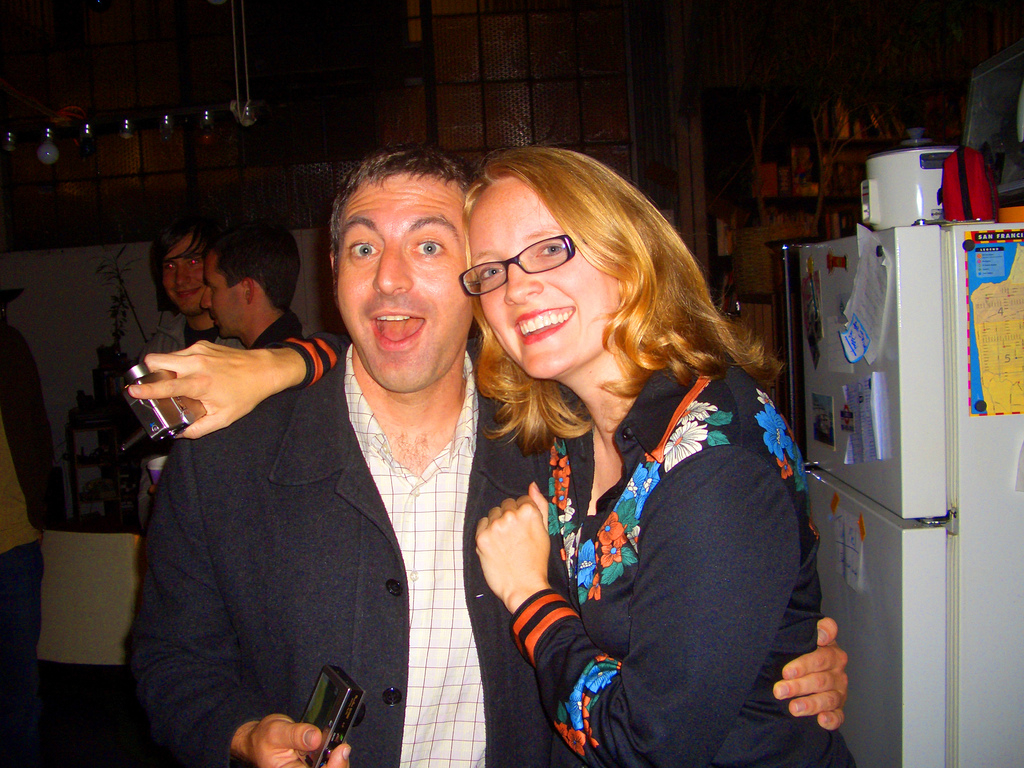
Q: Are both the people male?
A: No, they are both male and female.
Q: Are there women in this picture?
A: Yes, there is a woman.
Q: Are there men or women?
A: Yes, there is a woman.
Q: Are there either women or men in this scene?
A: Yes, there is a woman.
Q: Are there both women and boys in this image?
A: No, there is a woman but no boys.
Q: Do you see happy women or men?
A: Yes, there is a happy woman.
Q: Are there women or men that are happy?
A: Yes, the woman is happy.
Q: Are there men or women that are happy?
A: Yes, the woman is happy.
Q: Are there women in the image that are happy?
A: Yes, there is a happy woman.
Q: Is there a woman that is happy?
A: Yes, there is a woman that is happy.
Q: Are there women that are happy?
A: Yes, there is a woman that is happy.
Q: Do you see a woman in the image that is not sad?
A: Yes, there is a happy woman.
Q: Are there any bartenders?
A: No, there are no bartenders.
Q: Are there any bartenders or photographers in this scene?
A: No, there are no bartenders or photographers.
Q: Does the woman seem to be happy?
A: Yes, the woman is happy.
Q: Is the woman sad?
A: No, the woman is happy.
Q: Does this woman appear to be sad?
A: No, the woman is happy.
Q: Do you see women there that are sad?
A: No, there is a woman but she is happy.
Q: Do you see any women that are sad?
A: No, there is a woman but she is happy.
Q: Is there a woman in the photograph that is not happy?
A: No, there is a woman but she is happy.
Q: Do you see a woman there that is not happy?
A: No, there is a woman but she is happy.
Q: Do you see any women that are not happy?
A: No, there is a woman but she is happy.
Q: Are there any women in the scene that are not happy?
A: No, there is a woman but she is happy.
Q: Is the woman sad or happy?
A: The woman is happy.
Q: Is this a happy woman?
A: Yes, this is a happy woman.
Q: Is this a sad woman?
A: No, this is a happy woman.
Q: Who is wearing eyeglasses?
A: The woman is wearing eyeglasses.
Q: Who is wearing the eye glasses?
A: The woman is wearing eyeglasses.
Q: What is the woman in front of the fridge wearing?
A: The woman is wearing eyeglasses.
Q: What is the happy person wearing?
A: The woman is wearing eyeglasses.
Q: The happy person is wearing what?
A: The woman is wearing eyeglasses.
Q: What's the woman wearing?
A: The woman is wearing eyeglasses.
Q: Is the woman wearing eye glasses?
A: Yes, the woman is wearing eye glasses.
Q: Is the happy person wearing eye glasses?
A: Yes, the woman is wearing eye glasses.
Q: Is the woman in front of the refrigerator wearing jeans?
A: No, the woman is wearing eye glasses.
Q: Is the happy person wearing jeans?
A: No, the woman is wearing eye glasses.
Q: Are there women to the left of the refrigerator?
A: Yes, there is a woman to the left of the refrigerator.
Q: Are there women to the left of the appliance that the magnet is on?
A: Yes, there is a woman to the left of the refrigerator.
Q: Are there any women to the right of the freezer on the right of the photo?
A: No, the woman is to the left of the freezer.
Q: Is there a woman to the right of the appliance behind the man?
A: No, the woman is to the left of the freezer.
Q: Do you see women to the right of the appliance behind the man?
A: No, the woman is to the left of the freezer.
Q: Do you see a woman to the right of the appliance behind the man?
A: No, the woman is to the left of the freezer.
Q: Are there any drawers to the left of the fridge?
A: No, there is a woman to the left of the fridge.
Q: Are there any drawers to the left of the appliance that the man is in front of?
A: No, there is a woman to the left of the fridge.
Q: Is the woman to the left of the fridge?
A: Yes, the woman is to the left of the fridge.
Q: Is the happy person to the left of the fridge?
A: Yes, the woman is to the left of the fridge.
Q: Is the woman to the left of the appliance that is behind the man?
A: Yes, the woman is to the left of the fridge.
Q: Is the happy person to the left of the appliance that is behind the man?
A: Yes, the woman is to the left of the fridge.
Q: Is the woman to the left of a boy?
A: No, the woman is to the left of the fridge.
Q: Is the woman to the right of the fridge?
A: No, the woman is to the left of the fridge.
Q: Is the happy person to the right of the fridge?
A: No, the woman is to the left of the fridge.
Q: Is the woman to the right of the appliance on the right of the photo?
A: No, the woman is to the left of the fridge.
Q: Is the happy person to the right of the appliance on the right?
A: No, the woman is to the left of the fridge.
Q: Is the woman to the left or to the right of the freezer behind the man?
A: The woman is to the left of the refrigerator.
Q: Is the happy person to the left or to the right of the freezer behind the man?
A: The woman is to the left of the refrigerator.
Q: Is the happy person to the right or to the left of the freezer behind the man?
A: The woman is to the left of the refrigerator.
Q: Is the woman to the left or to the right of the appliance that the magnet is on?
A: The woman is to the left of the refrigerator.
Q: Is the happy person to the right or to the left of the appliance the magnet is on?
A: The woman is to the left of the refrigerator.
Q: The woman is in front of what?
A: The woman is in front of the fridge.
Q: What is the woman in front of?
A: The woman is in front of the fridge.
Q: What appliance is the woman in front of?
A: The woman is in front of the refrigerator.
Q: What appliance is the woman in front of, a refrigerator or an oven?
A: The woman is in front of a refrigerator.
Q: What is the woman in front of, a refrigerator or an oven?
A: The woman is in front of a refrigerator.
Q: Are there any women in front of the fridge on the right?
A: Yes, there is a woman in front of the refrigerator.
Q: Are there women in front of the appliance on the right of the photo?
A: Yes, there is a woman in front of the refrigerator.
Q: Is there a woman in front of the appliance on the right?
A: Yes, there is a woman in front of the refrigerator.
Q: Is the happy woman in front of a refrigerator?
A: Yes, the woman is in front of a refrigerator.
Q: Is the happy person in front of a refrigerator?
A: Yes, the woman is in front of a refrigerator.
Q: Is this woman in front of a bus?
A: No, the woman is in front of a refrigerator.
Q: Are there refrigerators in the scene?
A: Yes, there is a refrigerator.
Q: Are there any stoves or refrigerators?
A: Yes, there is a refrigerator.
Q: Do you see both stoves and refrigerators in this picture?
A: No, there is a refrigerator but no stoves.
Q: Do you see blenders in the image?
A: No, there are no blenders.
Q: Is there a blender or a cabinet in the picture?
A: No, there are no blenders or cabinets.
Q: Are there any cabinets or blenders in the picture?
A: No, there are no blenders or cabinets.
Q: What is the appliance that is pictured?
A: The appliance is a refrigerator.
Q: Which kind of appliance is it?
A: The appliance is a refrigerator.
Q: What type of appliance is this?
A: That is a refrigerator.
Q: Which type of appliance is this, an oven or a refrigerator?
A: That is a refrigerator.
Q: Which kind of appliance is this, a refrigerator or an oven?
A: That is a refrigerator.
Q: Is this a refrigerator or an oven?
A: This is a refrigerator.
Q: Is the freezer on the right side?
A: Yes, the freezer is on the right of the image.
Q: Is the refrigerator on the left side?
A: No, the refrigerator is on the right of the image.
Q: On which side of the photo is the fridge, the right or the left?
A: The fridge is on the right of the image.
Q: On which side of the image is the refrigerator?
A: The refrigerator is on the right of the image.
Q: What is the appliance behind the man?
A: The appliance is a refrigerator.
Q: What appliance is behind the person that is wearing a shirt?
A: The appliance is a refrigerator.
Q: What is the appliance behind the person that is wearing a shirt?
A: The appliance is a refrigerator.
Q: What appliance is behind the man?
A: The appliance is a refrigerator.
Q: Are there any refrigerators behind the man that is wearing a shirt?
A: Yes, there is a refrigerator behind the man.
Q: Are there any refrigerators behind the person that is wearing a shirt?
A: Yes, there is a refrigerator behind the man.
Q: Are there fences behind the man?
A: No, there is a refrigerator behind the man.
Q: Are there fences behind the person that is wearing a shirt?
A: No, there is a refrigerator behind the man.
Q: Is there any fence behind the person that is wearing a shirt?
A: No, there is a refrigerator behind the man.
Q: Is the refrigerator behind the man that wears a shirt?
A: Yes, the refrigerator is behind the man.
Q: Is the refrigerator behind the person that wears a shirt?
A: Yes, the refrigerator is behind the man.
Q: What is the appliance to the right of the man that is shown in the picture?
A: The appliance is a refrigerator.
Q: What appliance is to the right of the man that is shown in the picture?
A: The appliance is a refrigerator.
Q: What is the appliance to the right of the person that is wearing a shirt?
A: The appliance is a refrigerator.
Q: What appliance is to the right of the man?
A: The appliance is a refrigerator.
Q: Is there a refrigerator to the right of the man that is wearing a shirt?
A: Yes, there is a refrigerator to the right of the man.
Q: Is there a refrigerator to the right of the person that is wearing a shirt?
A: Yes, there is a refrigerator to the right of the man.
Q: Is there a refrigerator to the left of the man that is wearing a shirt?
A: No, the refrigerator is to the right of the man.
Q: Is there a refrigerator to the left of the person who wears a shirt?
A: No, the refrigerator is to the right of the man.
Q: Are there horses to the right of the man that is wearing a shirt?
A: No, there is a refrigerator to the right of the man.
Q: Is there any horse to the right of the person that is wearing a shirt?
A: No, there is a refrigerator to the right of the man.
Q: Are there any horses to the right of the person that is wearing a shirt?
A: No, there is a refrigerator to the right of the man.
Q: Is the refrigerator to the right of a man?
A: Yes, the refrigerator is to the right of a man.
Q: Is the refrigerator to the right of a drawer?
A: No, the refrigerator is to the right of a man.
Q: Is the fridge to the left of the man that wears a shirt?
A: No, the fridge is to the right of the man.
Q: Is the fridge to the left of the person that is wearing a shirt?
A: No, the fridge is to the right of the man.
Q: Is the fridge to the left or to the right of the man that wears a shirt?
A: The fridge is to the right of the man.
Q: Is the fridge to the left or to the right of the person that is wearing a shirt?
A: The fridge is to the right of the man.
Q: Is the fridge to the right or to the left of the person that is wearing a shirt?
A: The fridge is to the right of the man.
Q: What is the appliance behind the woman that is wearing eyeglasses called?
A: The appliance is a refrigerator.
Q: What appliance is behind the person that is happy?
A: The appliance is a refrigerator.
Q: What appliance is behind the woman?
A: The appliance is a refrigerator.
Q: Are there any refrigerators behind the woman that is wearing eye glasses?
A: Yes, there is a refrigerator behind the woman.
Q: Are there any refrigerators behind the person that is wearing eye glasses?
A: Yes, there is a refrigerator behind the woman.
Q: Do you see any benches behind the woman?
A: No, there is a refrigerator behind the woman.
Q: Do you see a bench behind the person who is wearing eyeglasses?
A: No, there is a refrigerator behind the woman.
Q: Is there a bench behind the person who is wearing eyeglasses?
A: No, there is a refrigerator behind the woman.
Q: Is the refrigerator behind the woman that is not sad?
A: Yes, the refrigerator is behind the woman.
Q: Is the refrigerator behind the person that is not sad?
A: Yes, the refrigerator is behind the woman.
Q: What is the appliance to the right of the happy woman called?
A: The appliance is a refrigerator.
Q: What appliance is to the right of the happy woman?
A: The appliance is a refrigerator.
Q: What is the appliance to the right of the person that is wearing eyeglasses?
A: The appliance is a refrigerator.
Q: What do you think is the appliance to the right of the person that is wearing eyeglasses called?
A: The appliance is a refrigerator.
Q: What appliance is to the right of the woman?
A: The appliance is a refrigerator.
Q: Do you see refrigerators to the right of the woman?
A: Yes, there is a refrigerator to the right of the woman.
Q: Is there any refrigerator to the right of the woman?
A: Yes, there is a refrigerator to the right of the woman.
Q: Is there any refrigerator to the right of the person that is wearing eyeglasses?
A: Yes, there is a refrigerator to the right of the woman.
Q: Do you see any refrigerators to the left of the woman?
A: No, the refrigerator is to the right of the woman.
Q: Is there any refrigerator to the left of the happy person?
A: No, the refrigerator is to the right of the woman.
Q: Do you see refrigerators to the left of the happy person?
A: No, the refrigerator is to the right of the woman.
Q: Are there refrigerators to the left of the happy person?
A: No, the refrigerator is to the right of the woman.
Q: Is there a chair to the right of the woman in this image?
A: No, there is a refrigerator to the right of the woman.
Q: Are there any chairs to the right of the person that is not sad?
A: No, there is a refrigerator to the right of the woman.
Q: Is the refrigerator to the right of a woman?
A: Yes, the refrigerator is to the right of a woman.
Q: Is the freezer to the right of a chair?
A: No, the freezer is to the right of a woman.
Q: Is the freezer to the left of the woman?
A: No, the freezer is to the right of the woman.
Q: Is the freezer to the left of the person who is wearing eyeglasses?
A: No, the freezer is to the right of the woman.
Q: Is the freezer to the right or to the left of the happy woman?
A: The freezer is to the right of the woman.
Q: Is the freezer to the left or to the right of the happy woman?
A: The freezer is to the right of the woman.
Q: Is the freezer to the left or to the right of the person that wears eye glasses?
A: The freezer is to the right of the woman.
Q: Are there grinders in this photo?
A: No, there are no grinders.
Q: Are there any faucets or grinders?
A: No, there are no grinders or faucets.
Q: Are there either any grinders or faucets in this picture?
A: No, there are no grinders or faucets.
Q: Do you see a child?
A: No, there are no children.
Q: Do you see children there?
A: No, there are no children.